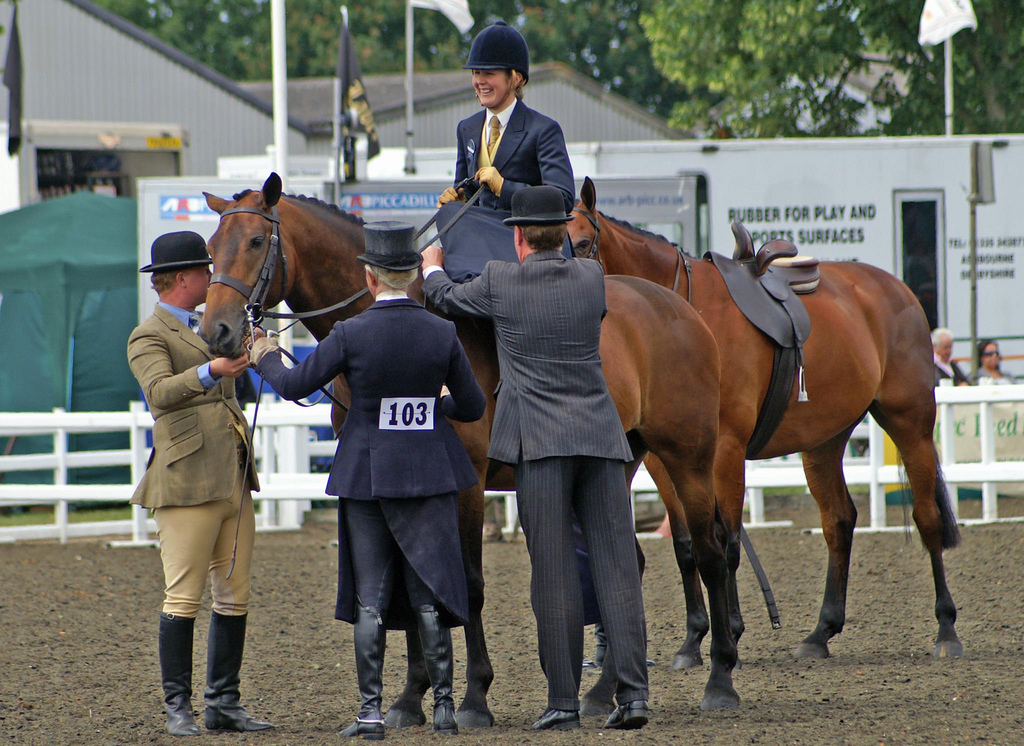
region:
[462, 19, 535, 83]
rider wearing a blue equestrian helmet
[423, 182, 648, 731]
black bowler hat on a man wearing a grey suit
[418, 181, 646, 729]
man wearing a grey suit and hat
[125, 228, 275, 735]
man wearing a green jacket and bowler hat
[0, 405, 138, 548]
white jumping fence for equestrian competition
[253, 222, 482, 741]
an equestrian rider wearing a top hat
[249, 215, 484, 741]
equestrian rider wearing black riding boots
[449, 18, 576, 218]
equestrian rider wearing a gold neck tie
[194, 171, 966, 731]
the horses are brown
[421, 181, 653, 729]
the man is wearing a suit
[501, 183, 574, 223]
the hat is black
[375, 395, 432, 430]
the white bib has the number 103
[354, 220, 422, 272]
the hat is black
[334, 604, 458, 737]
the boots are black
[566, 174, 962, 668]
the saddle on the horse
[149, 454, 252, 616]
the pants are light brown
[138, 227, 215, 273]
the hat is black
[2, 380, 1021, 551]
the fence is white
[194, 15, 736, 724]
the woman is sitting on the horse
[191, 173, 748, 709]
the horse is brown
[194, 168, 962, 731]
the two horses are brown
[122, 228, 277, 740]
the man is wearing brown pants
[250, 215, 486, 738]
the woman is wearing black boots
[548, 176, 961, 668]
the saddle is on the horse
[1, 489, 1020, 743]
the dirt is brown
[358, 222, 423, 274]
the top hat is black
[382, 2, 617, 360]
a woman riding a horse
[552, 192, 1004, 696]
a horse with no rider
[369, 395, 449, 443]
103 on the back of the jacket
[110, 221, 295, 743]
a man in a brown riding outfit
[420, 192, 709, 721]
a man helping the woman on to the horse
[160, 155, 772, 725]
a horse with a rider on top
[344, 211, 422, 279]
a black top hat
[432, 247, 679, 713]
a pin striped suit on a man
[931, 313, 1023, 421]
two people sitting beyond the fence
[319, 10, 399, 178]
a black and yellow flag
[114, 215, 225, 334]
the head of a man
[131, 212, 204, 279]
the hat of a man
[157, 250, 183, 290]
the ear of a man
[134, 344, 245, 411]
the arm of a man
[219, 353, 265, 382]
the hand of a man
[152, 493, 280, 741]
the pants of a man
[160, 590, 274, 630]
the knees of a man